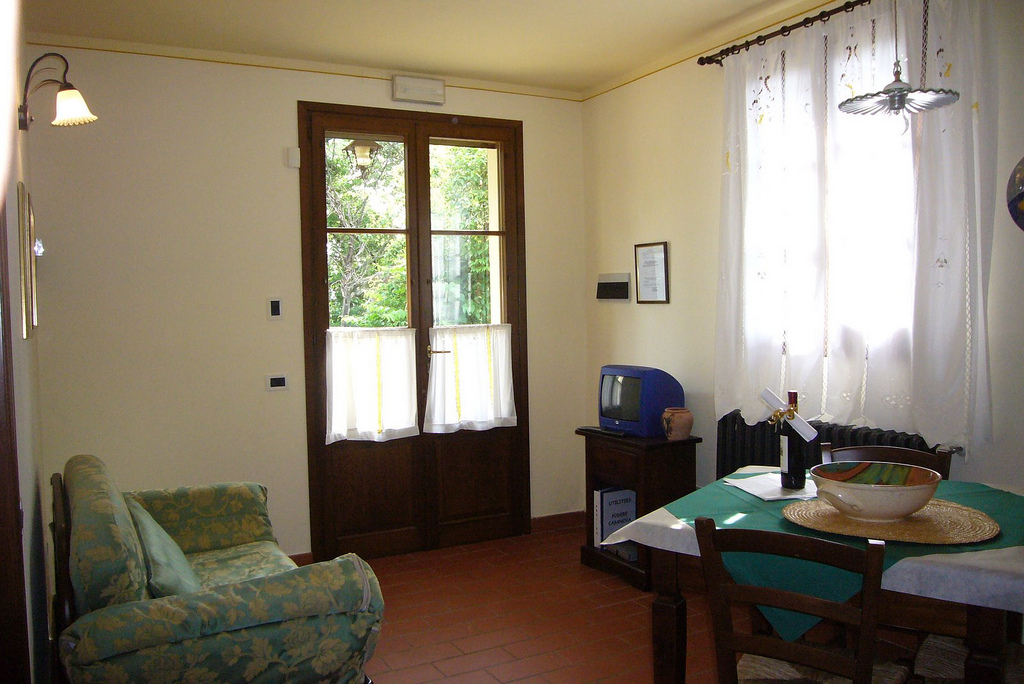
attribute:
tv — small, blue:
[595, 361, 684, 435]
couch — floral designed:
[48, 450, 390, 682]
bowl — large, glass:
[807, 457, 944, 525]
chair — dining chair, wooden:
[693, 511, 889, 682]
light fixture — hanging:
[836, 1, 960, 122]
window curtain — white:
[715, 1, 1007, 454]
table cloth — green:
[659, 473, 1023, 641]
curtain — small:
[321, 321, 420, 448]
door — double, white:
[425, 105, 531, 552]